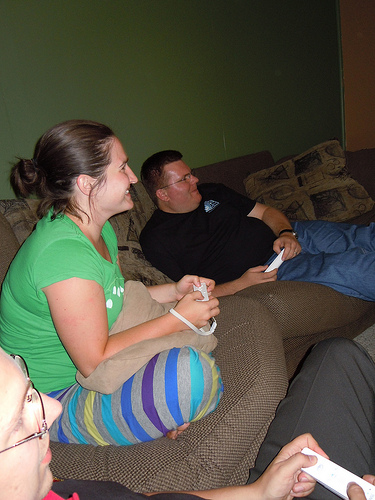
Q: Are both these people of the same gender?
A: No, they are both male and female.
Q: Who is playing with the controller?
A: The girl is playing with the controller.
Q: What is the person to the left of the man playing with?
A: The girl is playing with a controller.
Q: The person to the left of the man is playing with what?
A: The girl is playing with a controller.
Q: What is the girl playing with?
A: The girl is playing with a controller.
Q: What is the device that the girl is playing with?
A: The device is a controller.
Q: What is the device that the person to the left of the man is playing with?
A: The device is a controller.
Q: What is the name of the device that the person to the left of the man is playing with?
A: The device is a controller.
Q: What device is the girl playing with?
A: The girl is playing with a controller.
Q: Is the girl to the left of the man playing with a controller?
A: Yes, the girl is playing with a controller.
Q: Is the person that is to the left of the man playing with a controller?
A: Yes, the girl is playing with a controller.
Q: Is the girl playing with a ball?
A: No, the girl is playing with a controller.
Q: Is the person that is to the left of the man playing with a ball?
A: No, the girl is playing with a controller.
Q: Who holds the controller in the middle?
A: The girl holds the controller.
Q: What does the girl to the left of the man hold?
A: The girl holds the controller.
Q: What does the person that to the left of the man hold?
A: The girl holds the controller.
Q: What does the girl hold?
A: The girl holds the controller.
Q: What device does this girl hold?
A: The girl holds the controller.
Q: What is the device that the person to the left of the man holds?
A: The device is a controller.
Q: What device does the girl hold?
A: The girl holds the controller.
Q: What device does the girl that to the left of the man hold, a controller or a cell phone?
A: The girl holds a controller.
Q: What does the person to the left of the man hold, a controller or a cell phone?
A: The girl holds a controller.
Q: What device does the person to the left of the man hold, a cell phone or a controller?
A: The girl holds a controller.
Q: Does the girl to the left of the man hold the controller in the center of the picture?
A: Yes, the girl holds the controller.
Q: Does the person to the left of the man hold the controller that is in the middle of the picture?
A: Yes, the girl holds the controller.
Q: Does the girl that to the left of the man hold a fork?
A: No, the girl holds the controller.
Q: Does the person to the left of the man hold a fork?
A: No, the girl holds the controller.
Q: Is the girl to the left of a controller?
A: Yes, the girl is to the left of a controller.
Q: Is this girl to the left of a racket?
A: No, the girl is to the left of a controller.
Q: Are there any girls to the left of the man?
A: Yes, there is a girl to the left of the man.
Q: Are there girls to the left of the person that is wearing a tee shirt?
A: Yes, there is a girl to the left of the man.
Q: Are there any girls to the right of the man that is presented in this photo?
A: No, the girl is to the left of the man.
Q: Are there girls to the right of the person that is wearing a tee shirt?
A: No, the girl is to the left of the man.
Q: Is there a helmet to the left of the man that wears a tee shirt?
A: No, there is a girl to the left of the man.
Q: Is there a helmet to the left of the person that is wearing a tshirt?
A: No, there is a girl to the left of the man.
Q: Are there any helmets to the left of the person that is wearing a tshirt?
A: No, there is a girl to the left of the man.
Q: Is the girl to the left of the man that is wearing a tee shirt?
A: Yes, the girl is to the left of the man.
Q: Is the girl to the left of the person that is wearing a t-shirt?
A: Yes, the girl is to the left of the man.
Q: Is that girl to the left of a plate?
A: No, the girl is to the left of the man.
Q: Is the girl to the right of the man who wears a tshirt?
A: No, the girl is to the left of the man.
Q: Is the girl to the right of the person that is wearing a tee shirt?
A: No, the girl is to the left of the man.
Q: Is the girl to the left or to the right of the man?
A: The girl is to the left of the man.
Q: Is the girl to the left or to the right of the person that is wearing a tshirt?
A: The girl is to the left of the man.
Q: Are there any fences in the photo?
A: No, there are no fences.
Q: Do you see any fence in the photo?
A: No, there are no fences.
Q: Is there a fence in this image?
A: No, there are no fences.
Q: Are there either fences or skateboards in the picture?
A: No, there are no fences or skateboards.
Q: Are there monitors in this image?
A: No, there are no monitors.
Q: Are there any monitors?
A: No, there are no monitors.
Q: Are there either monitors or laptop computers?
A: No, there are no monitors or laptop computers.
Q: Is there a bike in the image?
A: No, there are no bikes.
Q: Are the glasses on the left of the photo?
A: Yes, the glasses are on the left of the image.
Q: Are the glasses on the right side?
A: No, the glasses are on the left of the image.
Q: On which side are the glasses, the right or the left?
A: The glasses are on the left of the image.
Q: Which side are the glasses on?
A: The glasses are on the left of the image.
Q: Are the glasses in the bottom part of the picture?
A: Yes, the glasses are in the bottom of the image.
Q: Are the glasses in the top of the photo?
A: No, the glasses are in the bottom of the image.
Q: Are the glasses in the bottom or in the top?
A: The glasses are in the bottom of the image.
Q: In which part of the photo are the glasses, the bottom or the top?
A: The glasses are in the bottom of the image.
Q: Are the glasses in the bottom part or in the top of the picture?
A: The glasses are in the bottom of the image.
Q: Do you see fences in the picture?
A: No, there are no fences.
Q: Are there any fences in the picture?
A: No, there are no fences.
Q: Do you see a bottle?
A: No, there are no bottles.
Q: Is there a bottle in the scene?
A: No, there are no bottles.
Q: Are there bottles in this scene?
A: No, there are no bottles.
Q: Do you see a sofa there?
A: Yes, there is a sofa.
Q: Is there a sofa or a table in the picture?
A: Yes, there is a sofa.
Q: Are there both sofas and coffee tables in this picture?
A: No, there is a sofa but no coffee tables.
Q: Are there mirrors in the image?
A: No, there are no mirrors.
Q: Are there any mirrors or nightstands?
A: No, there are no mirrors or nightstands.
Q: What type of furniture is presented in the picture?
A: The furniture is a sofa.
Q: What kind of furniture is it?
A: The piece of furniture is a sofa.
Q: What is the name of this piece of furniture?
A: This is a sofa.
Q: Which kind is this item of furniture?
A: This is a sofa.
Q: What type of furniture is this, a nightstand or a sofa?
A: This is a sofa.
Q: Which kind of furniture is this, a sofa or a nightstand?
A: This is a sofa.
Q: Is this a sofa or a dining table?
A: This is a sofa.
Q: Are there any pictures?
A: No, there are no pictures.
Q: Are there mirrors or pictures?
A: No, there are no pictures or mirrors.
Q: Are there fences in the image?
A: No, there are no fences.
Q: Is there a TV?
A: No, there are no televisions.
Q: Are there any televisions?
A: No, there are no televisions.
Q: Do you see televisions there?
A: No, there are no televisions.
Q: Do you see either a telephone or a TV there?
A: No, there are no televisions or phones.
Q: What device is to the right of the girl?
A: The device is a controller.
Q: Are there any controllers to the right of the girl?
A: Yes, there is a controller to the right of the girl.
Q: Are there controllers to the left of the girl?
A: No, the controller is to the right of the girl.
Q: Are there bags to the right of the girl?
A: No, there is a controller to the right of the girl.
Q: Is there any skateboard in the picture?
A: No, there are no skateboards.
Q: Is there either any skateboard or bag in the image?
A: No, there are no skateboards or bags.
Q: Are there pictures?
A: No, there are no pictures.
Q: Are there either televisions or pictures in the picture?
A: No, there are no pictures or televisions.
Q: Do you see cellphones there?
A: No, there are no cellphones.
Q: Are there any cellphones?
A: No, there are no cellphones.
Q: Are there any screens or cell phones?
A: No, there are no cell phones or screens.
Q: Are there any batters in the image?
A: No, there are no batters.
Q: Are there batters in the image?
A: No, there are no batters.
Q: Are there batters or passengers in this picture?
A: No, there are no batters or passengers.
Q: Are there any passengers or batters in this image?
A: No, there are no batters or passengers.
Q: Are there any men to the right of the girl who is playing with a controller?
A: Yes, there is a man to the right of the girl.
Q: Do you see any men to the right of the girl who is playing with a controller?
A: Yes, there is a man to the right of the girl.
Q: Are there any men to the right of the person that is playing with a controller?
A: Yes, there is a man to the right of the girl.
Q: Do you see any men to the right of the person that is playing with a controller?
A: Yes, there is a man to the right of the girl.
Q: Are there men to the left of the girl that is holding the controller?
A: No, the man is to the right of the girl.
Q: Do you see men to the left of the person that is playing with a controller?
A: No, the man is to the right of the girl.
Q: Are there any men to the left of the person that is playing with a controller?
A: No, the man is to the right of the girl.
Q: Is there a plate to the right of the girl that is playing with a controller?
A: No, there is a man to the right of the girl.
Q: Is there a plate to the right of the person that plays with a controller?
A: No, there is a man to the right of the girl.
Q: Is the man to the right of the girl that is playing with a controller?
A: Yes, the man is to the right of the girl.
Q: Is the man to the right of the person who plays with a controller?
A: Yes, the man is to the right of the girl.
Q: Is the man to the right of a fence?
A: No, the man is to the right of the girl.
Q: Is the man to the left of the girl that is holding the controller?
A: No, the man is to the right of the girl.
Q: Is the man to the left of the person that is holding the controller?
A: No, the man is to the right of the girl.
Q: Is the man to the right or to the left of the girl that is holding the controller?
A: The man is to the right of the girl.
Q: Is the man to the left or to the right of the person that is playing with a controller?
A: The man is to the right of the girl.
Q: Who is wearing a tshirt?
A: The man is wearing a tshirt.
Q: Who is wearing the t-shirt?
A: The man is wearing a tshirt.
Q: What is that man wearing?
A: The man is wearing a t-shirt.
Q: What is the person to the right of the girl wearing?
A: The man is wearing a t-shirt.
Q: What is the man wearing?
A: The man is wearing a t-shirt.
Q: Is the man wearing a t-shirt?
A: Yes, the man is wearing a t-shirt.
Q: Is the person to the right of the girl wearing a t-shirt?
A: Yes, the man is wearing a t-shirt.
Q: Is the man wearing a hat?
A: No, the man is wearing a t-shirt.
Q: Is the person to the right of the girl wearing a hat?
A: No, the man is wearing a t-shirt.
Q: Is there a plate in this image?
A: No, there are no plates.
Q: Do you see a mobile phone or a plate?
A: No, there are no plates or cell phones.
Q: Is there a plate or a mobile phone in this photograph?
A: No, there are no plates or cell phones.